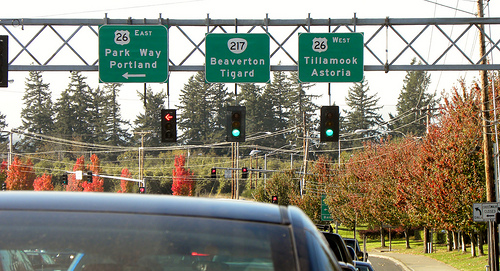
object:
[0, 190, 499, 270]
street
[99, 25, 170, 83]
signs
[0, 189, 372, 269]
traffic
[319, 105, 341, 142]
signals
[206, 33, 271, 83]
sign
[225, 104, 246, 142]
signal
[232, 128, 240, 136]
go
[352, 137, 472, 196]
leaves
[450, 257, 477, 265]
grass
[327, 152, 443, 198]
park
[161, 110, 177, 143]
light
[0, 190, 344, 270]
car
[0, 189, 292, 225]
hood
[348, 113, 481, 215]
trees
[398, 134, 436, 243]
tree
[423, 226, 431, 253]
trunk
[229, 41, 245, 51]
number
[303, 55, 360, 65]
tillamook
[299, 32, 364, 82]
sign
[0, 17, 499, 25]
pole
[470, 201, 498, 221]
sign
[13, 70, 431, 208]
pines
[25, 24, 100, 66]
support bars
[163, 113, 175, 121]
arrow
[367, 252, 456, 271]
sidewalk